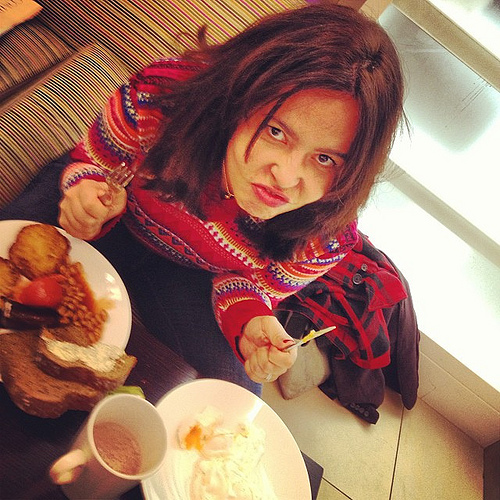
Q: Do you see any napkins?
A: No, there are no napkins.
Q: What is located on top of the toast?
A: The butter is on top of the toast.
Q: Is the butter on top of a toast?
A: Yes, the butter is on top of a toast.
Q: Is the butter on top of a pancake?
A: No, the butter is on top of a toast.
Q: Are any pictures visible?
A: No, there are no pictures.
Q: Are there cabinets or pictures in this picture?
A: No, there are no pictures or cabinets.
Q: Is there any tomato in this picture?
A: Yes, there is a tomato.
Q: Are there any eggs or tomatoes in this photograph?
A: Yes, there is a tomato.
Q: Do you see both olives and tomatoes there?
A: No, there is a tomato but no olives.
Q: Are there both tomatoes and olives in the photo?
A: No, there is a tomato but no olives.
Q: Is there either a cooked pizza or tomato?
A: Yes, there is a cooked tomato.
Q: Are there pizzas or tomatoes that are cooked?
A: Yes, the tomato is cooked.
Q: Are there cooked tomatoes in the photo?
A: Yes, there is a cooked tomato.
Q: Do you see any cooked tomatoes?
A: Yes, there is a cooked tomato.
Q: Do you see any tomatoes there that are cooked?
A: Yes, there is a tomato that is cooked.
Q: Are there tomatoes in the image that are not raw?
A: Yes, there is a cooked tomato.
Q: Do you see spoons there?
A: No, there are no spoons.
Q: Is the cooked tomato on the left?
A: Yes, the tomato is on the left of the image.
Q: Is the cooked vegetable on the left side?
A: Yes, the tomato is on the left of the image.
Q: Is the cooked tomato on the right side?
A: No, the tomato is on the left of the image.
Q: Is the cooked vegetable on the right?
A: No, the tomato is on the left of the image.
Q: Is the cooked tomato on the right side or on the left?
A: The tomato is on the left of the image.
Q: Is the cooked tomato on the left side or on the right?
A: The tomato is on the left of the image.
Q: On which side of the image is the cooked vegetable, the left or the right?
A: The tomato is on the left of the image.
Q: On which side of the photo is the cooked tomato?
A: The tomato is on the left of the image.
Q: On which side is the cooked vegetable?
A: The tomato is on the left of the image.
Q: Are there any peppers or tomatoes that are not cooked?
A: No, there is a tomato but it is cooked.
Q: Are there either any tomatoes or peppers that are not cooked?
A: No, there is a tomato but it is cooked.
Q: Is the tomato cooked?
A: Yes, the tomato is cooked.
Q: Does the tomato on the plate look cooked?
A: Yes, the tomato is cooked.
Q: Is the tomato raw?
A: No, the tomato is cooked.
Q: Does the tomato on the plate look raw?
A: No, the tomato is cooked.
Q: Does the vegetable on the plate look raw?
A: No, the tomato is cooked.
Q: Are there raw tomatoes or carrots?
A: No, there is a tomato but it is cooked.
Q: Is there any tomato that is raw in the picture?
A: No, there is a tomato but it is cooked.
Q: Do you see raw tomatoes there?
A: No, there is a tomato but it is cooked.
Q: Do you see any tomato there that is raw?
A: No, there is a tomato but it is cooked.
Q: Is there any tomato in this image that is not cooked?
A: No, there is a tomato but it is cooked.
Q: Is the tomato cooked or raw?
A: The tomato is cooked.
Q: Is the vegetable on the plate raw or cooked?
A: The tomato is cooked.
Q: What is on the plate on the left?
A: The tomato is on the plate.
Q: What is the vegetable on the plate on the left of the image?
A: The vegetable is a tomato.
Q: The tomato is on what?
A: The tomato is on the plate.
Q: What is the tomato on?
A: The tomato is on the plate.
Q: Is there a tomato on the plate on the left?
A: Yes, there is a tomato on the plate.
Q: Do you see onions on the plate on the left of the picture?
A: No, there is a tomato on the plate.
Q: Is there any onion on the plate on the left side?
A: No, there is a tomato on the plate.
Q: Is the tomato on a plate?
A: Yes, the tomato is on a plate.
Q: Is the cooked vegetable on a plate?
A: Yes, the tomato is on a plate.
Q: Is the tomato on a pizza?
A: No, the tomato is on a plate.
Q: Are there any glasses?
A: No, there are no glasses.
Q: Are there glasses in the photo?
A: No, there are no glasses.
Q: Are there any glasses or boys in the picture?
A: No, there are no glasses or boys.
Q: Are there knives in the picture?
A: Yes, there is a knife.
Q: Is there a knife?
A: Yes, there is a knife.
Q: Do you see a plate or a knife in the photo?
A: Yes, there is a knife.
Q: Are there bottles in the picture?
A: No, there are no bottles.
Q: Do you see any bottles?
A: No, there are no bottles.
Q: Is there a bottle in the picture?
A: No, there are no bottles.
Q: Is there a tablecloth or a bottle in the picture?
A: No, there are no bottles or tablecloths.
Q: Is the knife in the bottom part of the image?
A: Yes, the knife is in the bottom of the image.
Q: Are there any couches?
A: Yes, there is a couch.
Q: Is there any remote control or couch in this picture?
A: Yes, there is a couch.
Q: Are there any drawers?
A: No, there are no drawers.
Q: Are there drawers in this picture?
A: No, there are no drawers.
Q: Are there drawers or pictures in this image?
A: No, there are no drawers or pictures.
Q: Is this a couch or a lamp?
A: This is a couch.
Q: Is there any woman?
A: Yes, there is a woman.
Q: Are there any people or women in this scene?
A: Yes, there is a woman.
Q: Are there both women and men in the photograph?
A: No, there is a woman but no men.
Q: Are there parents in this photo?
A: No, there are no parents.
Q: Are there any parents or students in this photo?
A: No, there are no parents or students.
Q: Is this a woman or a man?
A: This is a woman.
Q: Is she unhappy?
A: Yes, the woman is unhappy.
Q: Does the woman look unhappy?
A: Yes, the woman is unhappy.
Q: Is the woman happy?
A: No, the woman is unhappy.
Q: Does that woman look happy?
A: No, the woman is unhappy.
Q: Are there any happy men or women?
A: No, there is a woman but she is unhappy.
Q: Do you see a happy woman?
A: No, there is a woman but she is unhappy.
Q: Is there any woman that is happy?
A: No, there is a woman but she is unhappy.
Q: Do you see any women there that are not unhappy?
A: No, there is a woman but she is unhappy.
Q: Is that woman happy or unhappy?
A: The woman is unhappy.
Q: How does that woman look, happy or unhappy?
A: The woman is unhappy.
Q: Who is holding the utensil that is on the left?
A: The woman is holding the fork.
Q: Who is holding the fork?
A: The woman is holding the fork.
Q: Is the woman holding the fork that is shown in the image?
A: Yes, the woman is holding the fork.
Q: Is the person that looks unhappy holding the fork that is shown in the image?
A: Yes, the woman is holding the fork.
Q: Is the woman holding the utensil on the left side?
A: Yes, the woman is holding the fork.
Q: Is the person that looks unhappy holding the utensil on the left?
A: Yes, the woman is holding the fork.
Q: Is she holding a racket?
A: No, the woman is holding the fork.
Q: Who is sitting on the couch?
A: The woman is sitting on the couch.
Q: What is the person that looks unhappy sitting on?
A: The woman is sitting on the couch.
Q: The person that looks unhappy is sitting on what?
A: The woman is sitting on the couch.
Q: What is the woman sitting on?
A: The woman is sitting on the couch.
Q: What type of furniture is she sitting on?
A: The woman is sitting on the couch.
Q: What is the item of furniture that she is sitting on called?
A: The piece of furniture is a couch.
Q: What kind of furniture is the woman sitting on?
A: The woman is sitting on the couch.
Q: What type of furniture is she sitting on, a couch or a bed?
A: The woman is sitting on a couch.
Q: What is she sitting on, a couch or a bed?
A: The woman is sitting on a couch.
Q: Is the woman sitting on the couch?
A: Yes, the woman is sitting on the couch.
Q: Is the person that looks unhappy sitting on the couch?
A: Yes, the woman is sitting on the couch.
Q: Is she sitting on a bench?
A: No, the woman is sitting on the couch.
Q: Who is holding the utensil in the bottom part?
A: The woman is holding the knife.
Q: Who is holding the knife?
A: The woman is holding the knife.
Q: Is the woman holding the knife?
A: Yes, the woman is holding the knife.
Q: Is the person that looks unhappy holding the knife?
A: Yes, the woman is holding the knife.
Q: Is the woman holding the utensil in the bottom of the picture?
A: Yes, the woman is holding the knife.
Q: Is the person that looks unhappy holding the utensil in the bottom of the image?
A: Yes, the woman is holding the knife.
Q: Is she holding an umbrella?
A: No, the woman is holding the knife.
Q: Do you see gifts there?
A: No, there are no gifts.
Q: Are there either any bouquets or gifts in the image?
A: No, there are no gifts or bouquets.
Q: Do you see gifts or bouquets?
A: No, there are no gifts or bouquets.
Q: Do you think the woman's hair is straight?
A: Yes, the hair is straight.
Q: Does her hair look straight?
A: Yes, the hair is straight.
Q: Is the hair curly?
A: No, the hair is straight.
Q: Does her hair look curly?
A: No, the hair is straight.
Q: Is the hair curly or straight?
A: The hair is straight.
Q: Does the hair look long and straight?
A: Yes, the hair is long and straight.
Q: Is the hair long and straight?
A: Yes, the hair is long and straight.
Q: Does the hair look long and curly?
A: No, the hair is long but straight.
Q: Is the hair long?
A: Yes, the hair is long.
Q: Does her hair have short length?
A: No, the hair is long.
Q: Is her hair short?
A: No, the hair is long.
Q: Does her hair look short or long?
A: The hair is long.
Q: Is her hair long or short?
A: The hair is long.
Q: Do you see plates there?
A: Yes, there is a plate.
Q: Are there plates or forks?
A: Yes, there is a plate.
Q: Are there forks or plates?
A: Yes, there is a plate.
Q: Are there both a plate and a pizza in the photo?
A: No, there is a plate but no pizzas.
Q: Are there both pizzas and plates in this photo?
A: No, there is a plate but no pizzas.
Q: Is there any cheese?
A: No, there is no cheese.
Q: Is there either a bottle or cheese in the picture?
A: No, there are no cheese or bottles.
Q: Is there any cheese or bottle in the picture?
A: No, there are no cheese or bottles.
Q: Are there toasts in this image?
A: Yes, there is a toast.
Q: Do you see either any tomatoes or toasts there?
A: Yes, there is a toast.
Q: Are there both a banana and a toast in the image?
A: No, there is a toast but no bananas.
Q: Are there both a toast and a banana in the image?
A: No, there is a toast but no bananas.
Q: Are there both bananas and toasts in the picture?
A: No, there is a toast but no bananas.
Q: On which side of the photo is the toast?
A: The toast is on the left of the image.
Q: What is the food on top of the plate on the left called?
A: The food is a toast.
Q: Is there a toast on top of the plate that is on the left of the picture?
A: Yes, there is a toast on top of the plate.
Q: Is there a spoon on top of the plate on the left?
A: No, there is a toast on top of the plate.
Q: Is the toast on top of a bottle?
A: No, the toast is on top of the plate.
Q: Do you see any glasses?
A: No, there are no glasses.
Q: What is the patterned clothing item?
A: The clothing item is a sweater.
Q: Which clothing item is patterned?
A: The clothing item is a sweater.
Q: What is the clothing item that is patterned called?
A: The clothing item is a sweater.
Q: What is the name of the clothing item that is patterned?
A: The clothing item is a sweater.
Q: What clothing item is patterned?
A: The clothing item is a sweater.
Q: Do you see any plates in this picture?
A: Yes, there is a plate.